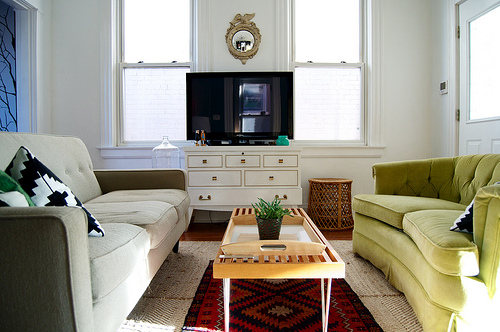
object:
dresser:
[187, 144, 303, 223]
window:
[294, 0, 365, 145]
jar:
[275, 133, 290, 146]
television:
[183, 71, 293, 145]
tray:
[220, 212, 327, 256]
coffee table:
[212, 202, 349, 329]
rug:
[182, 255, 384, 332]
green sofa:
[351, 150, 500, 330]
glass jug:
[149, 136, 184, 171]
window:
[111, 0, 191, 144]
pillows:
[2, 144, 105, 238]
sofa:
[0, 134, 197, 332]